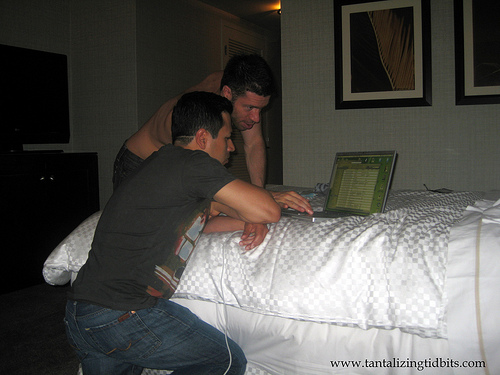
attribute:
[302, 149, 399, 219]
laptop — in the photo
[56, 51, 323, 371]
two people — in the photo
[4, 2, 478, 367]
photo — taken in a bedroom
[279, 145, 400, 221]
laptop — on the bed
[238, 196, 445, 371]
bed spread — white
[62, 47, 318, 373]
two males — looking at a laptop, in the photo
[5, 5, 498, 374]
picture — inside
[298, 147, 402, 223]
computer — working, laptop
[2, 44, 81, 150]
television — unused, flat screen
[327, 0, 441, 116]
art — abstract, wall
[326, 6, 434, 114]
frame — dark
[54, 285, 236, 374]
jeans — medium wash, blue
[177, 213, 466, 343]
cover — white, checkered, duvet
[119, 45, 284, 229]
man — shirtless, bending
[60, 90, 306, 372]
man — kneeling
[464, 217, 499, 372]
trim — off white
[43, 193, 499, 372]
sheets — white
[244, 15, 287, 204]
door — vented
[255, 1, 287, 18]
light — hall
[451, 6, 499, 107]
picture — hanging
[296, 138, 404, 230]
computer — on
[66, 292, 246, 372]
jeans — blue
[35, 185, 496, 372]
spread — bed, white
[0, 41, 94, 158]
television — off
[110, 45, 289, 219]
man — shirtless, standing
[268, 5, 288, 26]
light — on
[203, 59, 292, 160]
man — young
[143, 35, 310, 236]
men — young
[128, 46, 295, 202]
men — young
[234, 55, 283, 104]
hair — dark colored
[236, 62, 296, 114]
hair — dark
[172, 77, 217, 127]
hair — dark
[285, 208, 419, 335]
comforter — white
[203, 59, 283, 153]
male — shirtless